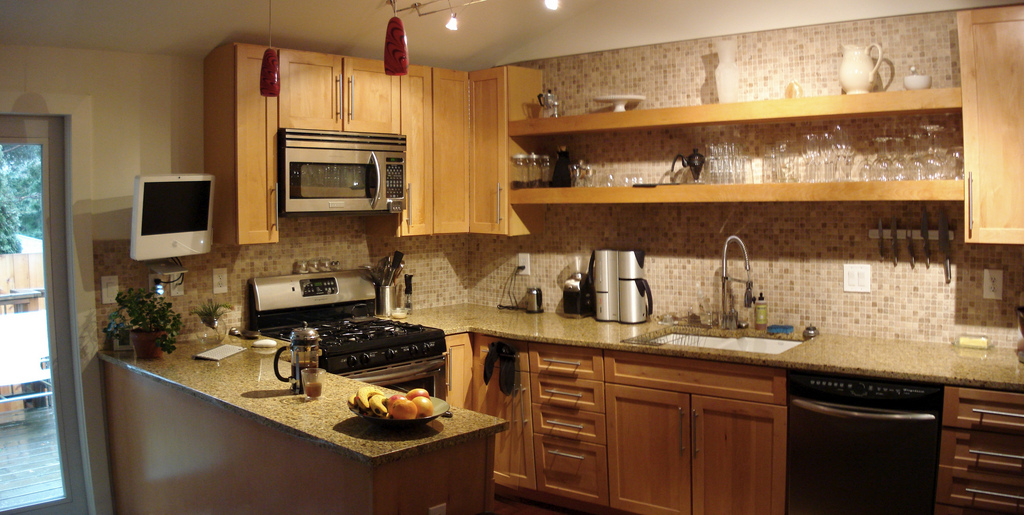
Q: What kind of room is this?
A: It is a kitchen.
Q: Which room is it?
A: It is a kitchen.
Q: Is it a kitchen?
A: Yes, it is a kitchen.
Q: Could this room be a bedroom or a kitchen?
A: It is a kitchen.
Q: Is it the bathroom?
A: No, it is the kitchen.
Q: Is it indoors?
A: Yes, it is indoors.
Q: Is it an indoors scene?
A: Yes, it is indoors.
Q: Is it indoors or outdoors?
A: It is indoors.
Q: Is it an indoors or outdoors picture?
A: It is indoors.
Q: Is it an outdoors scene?
A: No, it is indoors.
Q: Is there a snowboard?
A: No, there are no snowboards.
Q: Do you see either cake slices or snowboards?
A: No, there are no snowboards or cake slices.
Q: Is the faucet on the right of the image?
A: Yes, the faucet is on the right of the image.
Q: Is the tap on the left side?
A: No, the tap is on the right of the image.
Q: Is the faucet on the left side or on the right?
A: The faucet is on the right of the image.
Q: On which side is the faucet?
A: The faucet is on the right of the image.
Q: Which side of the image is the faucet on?
A: The faucet is on the right of the image.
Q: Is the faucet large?
A: Yes, the faucet is large.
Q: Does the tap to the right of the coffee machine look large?
A: Yes, the tap is large.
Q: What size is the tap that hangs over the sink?
A: The faucet is large.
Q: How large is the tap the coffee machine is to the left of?
A: The tap is large.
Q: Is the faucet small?
A: No, the faucet is large.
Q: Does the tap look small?
A: No, the tap is large.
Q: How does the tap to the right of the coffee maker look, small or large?
A: The faucet is large.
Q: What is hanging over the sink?
A: The faucet is hanging over the sink.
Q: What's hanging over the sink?
A: The faucet is hanging over the sink.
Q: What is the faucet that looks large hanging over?
A: The faucet is hanging over the sink.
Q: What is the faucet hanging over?
A: The faucet is hanging over the sink.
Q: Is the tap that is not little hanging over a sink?
A: Yes, the faucet is hanging over a sink.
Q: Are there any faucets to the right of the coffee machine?
A: Yes, there is a faucet to the right of the coffee machine.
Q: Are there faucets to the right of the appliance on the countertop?
A: Yes, there is a faucet to the right of the coffee machine.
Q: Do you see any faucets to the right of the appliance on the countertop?
A: Yes, there is a faucet to the right of the coffee machine.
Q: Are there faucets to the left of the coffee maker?
A: No, the faucet is to the right of the coffee maker.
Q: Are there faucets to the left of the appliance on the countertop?
A: No, the faucet is to the right of the coffee maker.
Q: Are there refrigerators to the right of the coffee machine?
A: No, there is a faucet to the right of the coffee machine.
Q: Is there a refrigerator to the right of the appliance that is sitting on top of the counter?
A: No, there is a faucet to the right of the coffee machine.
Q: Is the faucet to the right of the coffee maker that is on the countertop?
A: Yes, the faucet is to the right of the coffee machine.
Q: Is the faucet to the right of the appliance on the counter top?
A: Yes, the faucet is to the right of the coffee machine.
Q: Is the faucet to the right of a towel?
A: No, the faucet is to the right of the coffee machine.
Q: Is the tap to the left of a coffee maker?
A: No, the tap is to the right of a coffee maker.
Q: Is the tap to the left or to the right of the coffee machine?
A: The tap is to the right of the coffee machine.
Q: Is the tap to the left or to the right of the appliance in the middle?
A: The tap is to the right of the coffee machine.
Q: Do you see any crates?
A: No, there are no crates.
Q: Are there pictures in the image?
A: No, there are no pictures.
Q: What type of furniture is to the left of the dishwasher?
A: The piece of furniture is a drawer.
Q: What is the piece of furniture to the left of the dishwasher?
A: The piece of furniture is a drawer.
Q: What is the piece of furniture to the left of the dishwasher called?
A: The piece of furniture is a drawer.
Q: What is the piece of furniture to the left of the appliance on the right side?
A: The piece of furniture is a drawer.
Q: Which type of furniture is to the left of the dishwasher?
A: The piece of furniture is a drawer.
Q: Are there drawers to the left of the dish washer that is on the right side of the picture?
A: Yes, there is a drawer to the left of the dishwasher.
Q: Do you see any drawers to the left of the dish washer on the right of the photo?
A: Yes, there is a drawer to the left of the dishwasher.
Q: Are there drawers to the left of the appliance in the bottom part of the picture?
A: Yes, there is a drawer to the left of the dishwasher.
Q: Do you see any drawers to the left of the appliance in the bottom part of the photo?
A: Yes, there is a drawer to the left of the dishwasher.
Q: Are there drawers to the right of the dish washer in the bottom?
A: No, the drawer is to the left of the dishwasher.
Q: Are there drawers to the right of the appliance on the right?
A: No, the drawer is to the left of the dishwasher.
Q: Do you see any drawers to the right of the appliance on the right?
A: No, the drawer is to the left of the dishwasher.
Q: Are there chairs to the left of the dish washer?
A: No, there is a drawer to the left of the dish washer.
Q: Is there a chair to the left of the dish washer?
A: No, there is a drawer to the left of the dish washer.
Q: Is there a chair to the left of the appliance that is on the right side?
A: No, there is a drawer to the left of the dish washer.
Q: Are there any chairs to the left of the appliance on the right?
A: No, there is a drawer to the left of the dish washer.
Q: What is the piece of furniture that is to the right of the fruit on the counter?
A: The piece of furniture is a drawer.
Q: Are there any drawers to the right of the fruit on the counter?
A: Yes, there is a drawer to the right of the fruit.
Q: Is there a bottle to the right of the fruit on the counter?
A: No, there is a drawer to the right of the fruit.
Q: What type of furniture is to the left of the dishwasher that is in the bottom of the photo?
A: The piece of furniture is a drawer.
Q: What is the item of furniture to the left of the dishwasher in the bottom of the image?
A: The piece of furniture is a drawer.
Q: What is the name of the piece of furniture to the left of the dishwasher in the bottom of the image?
A: The piece of furniture is a drawer.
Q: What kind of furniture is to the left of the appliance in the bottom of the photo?
A: The piece of furniture is a drawer.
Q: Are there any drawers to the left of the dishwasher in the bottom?
A: Yes, there is a drawer to the left of the dishwasher.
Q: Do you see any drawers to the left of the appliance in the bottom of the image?
A: Yes, there is a drawer to the left of the dishwasher.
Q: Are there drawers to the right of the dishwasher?
A: No, the drawer is to the left of the dishwasher.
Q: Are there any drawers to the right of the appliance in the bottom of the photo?
A: No, the drawer is to the left of the dishwasher.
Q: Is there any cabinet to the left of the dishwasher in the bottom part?
A: No, there is a drawer to the left of the dishwasher.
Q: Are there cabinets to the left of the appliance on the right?
A: No, there is a drawer to the left of the dishwasher.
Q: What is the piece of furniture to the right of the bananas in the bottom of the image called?
A: The piece of furniture is a drawer.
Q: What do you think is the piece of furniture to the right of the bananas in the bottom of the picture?
A: The piece of furniture is a drawer.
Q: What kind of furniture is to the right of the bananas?
A: The piece of furniture is a drawer.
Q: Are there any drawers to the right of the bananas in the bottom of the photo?
A: Yes, there is a drawer to the right of the bananas.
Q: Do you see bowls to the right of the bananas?
A: No, there is a drawer to the right of the bananas.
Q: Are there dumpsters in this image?
A: No, there are no dumpsters.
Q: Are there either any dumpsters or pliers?
A: No, there are no dumpsters or pliers.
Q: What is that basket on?
A: The basket is on the counter.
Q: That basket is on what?
A: The basket is on the counter.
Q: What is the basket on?
A: The basket is on the counter.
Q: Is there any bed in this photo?
A: No, there are no beds.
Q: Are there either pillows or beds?
A: No, there are no beds or pillows.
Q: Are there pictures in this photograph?
A: No, there are no pictures.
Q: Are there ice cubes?
A: No, there are no ice cubes.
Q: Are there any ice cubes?
A: No, there are no ice cubes.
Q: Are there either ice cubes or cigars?
A: No, there are no ice cubes or cigars.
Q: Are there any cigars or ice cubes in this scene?
A: No, there are no ice cubes or cigars.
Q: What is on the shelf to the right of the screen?
A: The glass is on the shelf.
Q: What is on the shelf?
A: The glass is on the shelf.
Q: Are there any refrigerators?
A: No, there are no refrigerators.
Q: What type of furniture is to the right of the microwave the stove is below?
A: The piece of furniture is a shelf.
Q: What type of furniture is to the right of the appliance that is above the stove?
A: The piece of furniture is a shelf.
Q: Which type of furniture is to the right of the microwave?
A: The piece of furniture is a shelf.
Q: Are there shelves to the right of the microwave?
A: Yes, there is a shelf to the right of the microwave.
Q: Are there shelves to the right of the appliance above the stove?
A: Yes, there is a shelf to the right of the microwave.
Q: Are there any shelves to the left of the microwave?
A: No, the shelf is to the right of the microwave.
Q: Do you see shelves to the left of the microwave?
A: No, the shelf is to the right of the microwave.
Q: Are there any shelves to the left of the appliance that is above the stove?
A: No, the shelf is to the right of the microwave.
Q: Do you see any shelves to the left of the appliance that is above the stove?
A: No, the shelf is to the right of the microwave.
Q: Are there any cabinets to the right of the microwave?
A: No, there is a shelf to the right of the microwave.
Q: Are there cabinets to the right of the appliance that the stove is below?
A: No, there is a shelf to the right of the microwave.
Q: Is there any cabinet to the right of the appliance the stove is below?
A: No, there is a shelf to the right of the microwave.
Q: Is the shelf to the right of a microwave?
A: Yes, the shelf is to the right of a microwave.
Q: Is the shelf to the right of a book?
A: No, the shelf is to the right of a microwave.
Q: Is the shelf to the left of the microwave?
A: No, the shelf is to the right of the microwave.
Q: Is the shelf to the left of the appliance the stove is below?
A: No, the shelf is to the right of the microwave.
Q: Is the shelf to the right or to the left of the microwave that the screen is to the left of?
A: The shelf is to the right of the microwave.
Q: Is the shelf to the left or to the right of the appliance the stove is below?
A: The shelf is to the right of the microwave.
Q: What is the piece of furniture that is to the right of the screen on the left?
A: The piece of furniture is a shelf.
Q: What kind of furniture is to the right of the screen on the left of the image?
A: The piece of furniture is a shelf.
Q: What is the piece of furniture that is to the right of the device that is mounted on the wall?
A: The piece of furniture is a shelf.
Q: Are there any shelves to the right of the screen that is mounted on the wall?
A: Yes, there is a shelf to the right of the screen.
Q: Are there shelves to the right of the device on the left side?
A: Yes, there is a shelf to the right of the screen.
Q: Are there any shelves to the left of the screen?
A: No, the shelf is to the right of the screen.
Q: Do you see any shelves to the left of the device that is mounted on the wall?
A: No, the shelf is to the right of the screen.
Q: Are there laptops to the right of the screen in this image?
A: No, there is a shelf to the right of the screen.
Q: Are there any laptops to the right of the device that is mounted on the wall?
A: No, there is a shelf to the right of the screen.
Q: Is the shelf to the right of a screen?
A: Yes, the shelf is to the right of a screen.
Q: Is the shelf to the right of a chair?
A: No, the shelf is to the right of a screen.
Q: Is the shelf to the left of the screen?
A: No, the shelf is to the right of the screen.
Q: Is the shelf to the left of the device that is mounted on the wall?
A: No, the shelf is to the right of the screen.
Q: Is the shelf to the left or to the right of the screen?
A: The shelf is to the right of the screen.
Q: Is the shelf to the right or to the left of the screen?
A: The shelf is to the right of the screen.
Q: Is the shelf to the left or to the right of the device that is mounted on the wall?
A: The shelf is to the right of the screen.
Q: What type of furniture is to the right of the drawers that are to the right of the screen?
A: The piece of furniture is a shelf.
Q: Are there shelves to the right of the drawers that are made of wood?
A: Yes, there is a shelf to the right of the drawers.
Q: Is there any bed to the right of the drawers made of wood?
A: No, there is a shelf to the right of the drawers.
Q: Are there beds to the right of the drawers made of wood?
A: No, there is a shelf to the right of the drawers.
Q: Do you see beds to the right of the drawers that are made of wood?
A: No, there is a shelf to the right of the drawers.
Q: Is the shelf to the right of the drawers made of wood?
A: Yes, the shelf is to the right of the drawers.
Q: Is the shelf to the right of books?
A: No, the shelf is to the right of the drawers.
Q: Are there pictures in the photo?
A: No, there are no pictures.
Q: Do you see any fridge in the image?
A: No, there are no refrigerators.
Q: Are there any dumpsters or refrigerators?
A: No, there are no refrigerators or dumpsters.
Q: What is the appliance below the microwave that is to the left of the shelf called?
A: The appliance is a stove.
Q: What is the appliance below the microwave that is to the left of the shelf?
A: The appliance is a stove.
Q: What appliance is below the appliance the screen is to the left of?
A: The appliance is a stove.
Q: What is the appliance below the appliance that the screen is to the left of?
A: The appliance is a stove.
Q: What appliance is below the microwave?
A: The appliance is a stove.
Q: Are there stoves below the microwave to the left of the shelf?
A: Yes, there is a stove below the microwave.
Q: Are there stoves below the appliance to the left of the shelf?
A: Yes, there is a stove below the microwave.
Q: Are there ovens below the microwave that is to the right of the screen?
A: No, there is a stove below the microwave.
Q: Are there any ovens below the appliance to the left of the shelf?
A: No, there is a stove below the microwave.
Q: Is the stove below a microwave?
A: Yes, the stove is below a microwave.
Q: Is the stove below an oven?
A: No, the stove is below a microwave.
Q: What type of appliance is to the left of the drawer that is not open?
A: The appliance is a stove.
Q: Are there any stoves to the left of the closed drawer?
A: Yes, there is a stove to the left of the drawer.